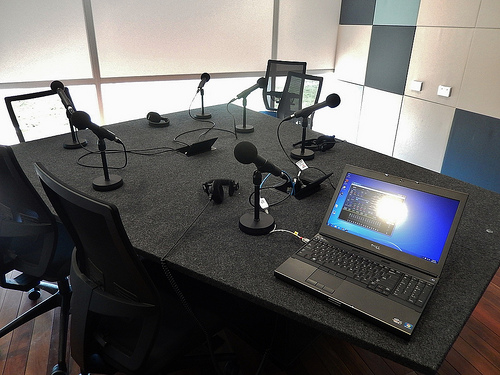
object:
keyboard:
[291, 235, 436, 312]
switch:
[437, 85, 452, 97]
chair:
[31, 161, 252, 375]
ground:
[361, 152, 388, 189]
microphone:
[196, 73, 210, 94]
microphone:
[294, 93, 341, 119]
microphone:
[71, 111, 124, 144]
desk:
[9, 103, 500, 375]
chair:
[276, 71, 324, 130]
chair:
[258, 59, 306, 121]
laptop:
[295, 238, 434, 306]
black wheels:
[239, 211, 274, 236]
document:
[338, 183, 407, 236]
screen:
[326, 172, 459, 264]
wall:
[0, 0, 500, 195]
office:
[0, 0, 499, 375]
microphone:
[51, 80, 75, 114]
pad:
[306, 266, 347, 294]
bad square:
[7, 102, 500, 375]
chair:
[0, 146, 72, 375]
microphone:
[234, 141, 289, 182]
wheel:
[28, 291, 41, 300]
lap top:
[295, 235, 447, 310]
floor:
[0, 270, 499, 375]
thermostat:
[410, 80, 423, 91]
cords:
[75, 92, 238, 169]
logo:
[391, 317, 413, 331]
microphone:
[257, 77, 268, 88]